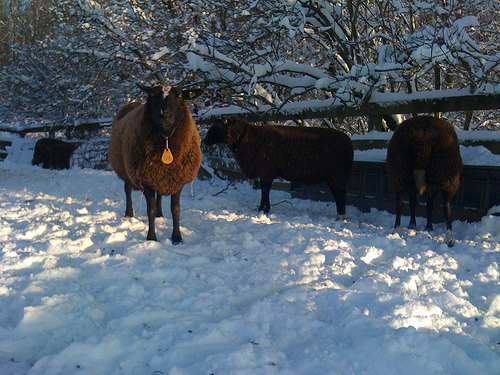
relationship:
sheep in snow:
[202, 114, 380, 226] [4, 170, 498, 370]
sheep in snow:
[107, 82, 204, 244] [4, 170, 498, 370]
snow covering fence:
[1, 179, 486, 351] [2, 87, 499, 227]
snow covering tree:
[1, 179, 486, 351] [8, 4, 459, 121]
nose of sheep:
[156, 109, 179, 127] [107, 82, 204, 244]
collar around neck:
[154, 134, 174, 167] [131, 107, 193, 140]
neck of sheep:
[131, 107, 193, 140] [95, 79, 202, 260]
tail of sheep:
[410, 137, 430, 204] [384, 112, 466, 233]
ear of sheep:
[135, 74, 154, 92] [35, 68, 270, 246]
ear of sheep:
[177, 81, 206, 101] [35, 68, 270, 246]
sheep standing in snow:
[107, 82, 204, 244] [4, 170, 498, 370]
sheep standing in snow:
[202, 114, 354, 222] [4, 170, 498, 370]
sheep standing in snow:
[385, 114, 462, 245] [4, 170, 498, 370]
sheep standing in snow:
[385, 114, 462, 245] [0, 149, 497, 374]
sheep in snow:
[202, 114, 354, 222] [4, 170, 498, 370]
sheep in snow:
[385, 114, 462, 245] [4, 170, 498, 370]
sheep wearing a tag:
[107, 82, 204, 244] [151, 124, 178, 164]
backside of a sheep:
[392, 124, 460, 203] [376, 108, 470, 240]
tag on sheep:
[157, 145, 179, 171] [107, 82, 204, 244]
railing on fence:
[206, 102, 499, 121] [14, 84, 499, 154]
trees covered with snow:
[5, 6, 493, 98] [4, 170, 498, 370]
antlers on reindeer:
[138, 65, 202, 121] [92, 73, 213, 245]